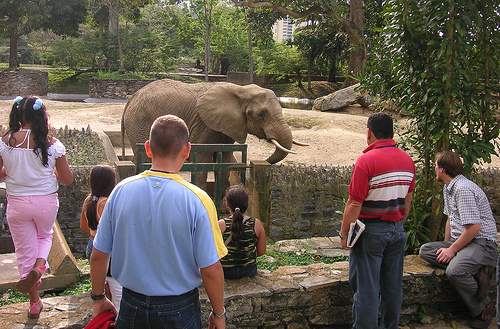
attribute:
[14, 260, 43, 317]
foot — one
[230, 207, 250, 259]
hair — long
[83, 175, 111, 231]
hair — long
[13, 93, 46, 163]
hair — long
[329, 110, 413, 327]
man — in the picture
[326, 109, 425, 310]
man — in the picture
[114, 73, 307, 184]
elephant — in the picture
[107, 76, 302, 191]
elephant — in the picture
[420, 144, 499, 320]
gentleman — gray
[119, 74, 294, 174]
elephant — in the picture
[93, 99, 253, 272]
guy — buzz cut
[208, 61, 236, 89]
ground — in the picture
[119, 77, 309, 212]
elephant — in the picture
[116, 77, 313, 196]
elephant — in the picture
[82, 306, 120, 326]
straps — red